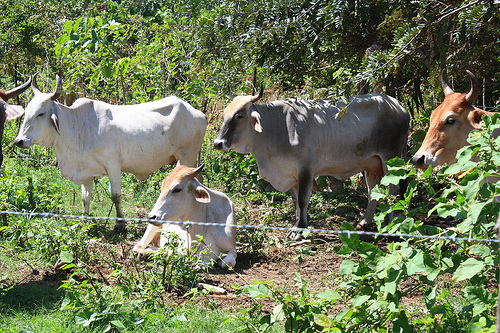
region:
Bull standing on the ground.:
[212, 77, 413, 234]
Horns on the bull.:
[222, 79, 267, 106]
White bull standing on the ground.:
[18, 67, 213, 242]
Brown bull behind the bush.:
[410, 70, 499, 172]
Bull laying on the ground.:
[128, 155, 242, 277]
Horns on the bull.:
[27, 68, 64, 102]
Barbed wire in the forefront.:
[1, 200, 498, 267]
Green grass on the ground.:
[0, 287, 256, 332]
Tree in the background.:
[195, 0, 497, 115]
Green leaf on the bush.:
[449, 255, 481, 280]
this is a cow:
[211, 75, 417, 235]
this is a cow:
[131, 150, 266, 275]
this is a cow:
[16, 76, 206, 213]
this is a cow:
[387, 80, 492, 230]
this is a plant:
[42, 236, 142, 322]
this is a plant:
[213, 265, 321, 330]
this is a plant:
[338, 201, 488, 327]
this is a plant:
[140, 62, 248, 155]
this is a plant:
[225, 192, 311, 297]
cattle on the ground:
[1, 77, 493, 269]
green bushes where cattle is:
[0, 1, 496, 330]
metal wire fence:
[1, 205, 497, 247]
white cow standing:
[15, 77, 207, 234]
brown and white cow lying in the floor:
[133, 161, 240, 275]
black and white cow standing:
[217, 87, 417, 239]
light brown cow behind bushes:
[414, 86, 496, 191]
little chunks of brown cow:
[434, 82, 479, 97]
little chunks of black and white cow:
[226, 82, 263, 96]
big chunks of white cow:
[27, 71, 64, 93]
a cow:
[24, 78, 209, 172]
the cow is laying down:
[138, 171, 243, 281]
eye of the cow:
[171, 180, 182, 195]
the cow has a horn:
[50, 75, 63, 97]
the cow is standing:
[220, 93, 416, 177]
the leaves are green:
[349, 233, 413, 292]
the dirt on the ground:
[247, 261, 285, 290]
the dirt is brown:
[257, 262, 283, 286]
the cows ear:
[188, 185, 216, 206]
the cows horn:
[459, 70, 484, 100]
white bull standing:
[16, 71, 208, 233]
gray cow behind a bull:
[213, 84, 411, 231]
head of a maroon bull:
[409, 68, 499, 175]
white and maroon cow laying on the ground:
[131, 160, 236, 269]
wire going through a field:
[0, 211, 499, 243]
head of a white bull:
[15, 74, 63, 146]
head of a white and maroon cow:
[148, 160, 204, 225]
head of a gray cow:
[212, 84, 264, 151]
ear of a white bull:
[50, 113, 60, 133]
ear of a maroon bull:
[468, 109, 489, 127]